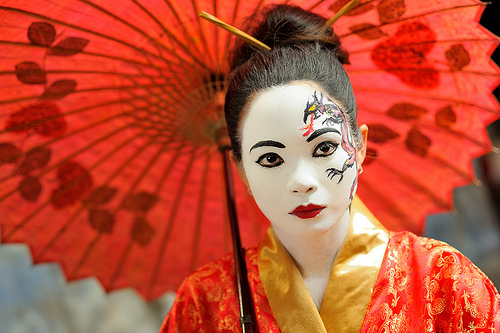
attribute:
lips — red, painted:
[283, 201, 344, 233]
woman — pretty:
[159, 3, 499, 331]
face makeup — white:
[239, 82, 359, 311]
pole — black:
[221, 159, 250, 321]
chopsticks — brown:
[199, 9, 358, 47]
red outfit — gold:
[159, 228, 497, 330]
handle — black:
[212, 144, 259, 330]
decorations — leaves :
[5, 18, 165, 247]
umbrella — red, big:
[7, 4, 222, 255]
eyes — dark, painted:
[248, 128, 346, 170]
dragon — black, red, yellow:
[302, 96, 366, 177]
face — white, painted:
[241, 91, 357, 233]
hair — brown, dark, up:
[258, 56, 339, 78]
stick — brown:
[195, 10, 274, 51]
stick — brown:
[327, 2, 360, 32]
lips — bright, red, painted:
[283, 199, 331, 221]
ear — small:
[354, 123, 375, 172]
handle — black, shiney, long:
[220, 148, 258, 330]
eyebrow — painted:
[304, 127, 345, 142]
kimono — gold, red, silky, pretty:
[159, 236, 498, 331]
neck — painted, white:
[275, 233, 348, 282]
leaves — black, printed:
[42, 153, 167, 249]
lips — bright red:
[284, 200, 329, 220]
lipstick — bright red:
[286, 201, 328, 220]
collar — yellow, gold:
[264, 245, 376, 330]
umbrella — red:
[2, 5, 484, 296]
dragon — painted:
[303, 91, 360, 199]